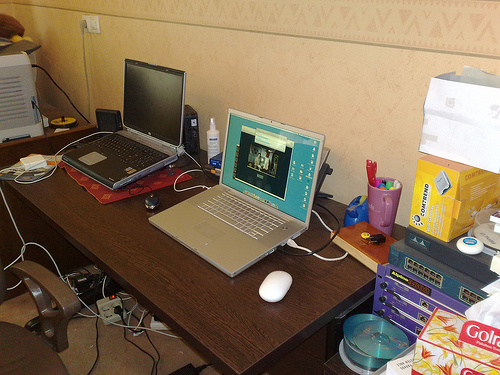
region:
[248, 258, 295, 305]
mouse on the desk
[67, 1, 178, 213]
Black laptop on the desk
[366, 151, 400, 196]
markers in the cup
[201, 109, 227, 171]
bottle on the desk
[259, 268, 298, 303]
The white mouse on the table.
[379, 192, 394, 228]
The handle of the purple cup.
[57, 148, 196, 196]
The red mat under the laptop.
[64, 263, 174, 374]
The wires under the table.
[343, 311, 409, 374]
The stack of CDs on the side table.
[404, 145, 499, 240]
The yellow box on the right.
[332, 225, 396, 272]
The book in front of the purple cup.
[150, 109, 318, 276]
The laptop on the right.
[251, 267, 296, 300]
white mouse on the desk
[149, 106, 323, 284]
open silver laptop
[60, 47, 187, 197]
open black and silver laptop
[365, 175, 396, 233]
purple cup on the table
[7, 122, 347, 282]
cords on the desk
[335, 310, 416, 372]
spindle of blue cds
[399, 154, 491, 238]
yellow cardboard box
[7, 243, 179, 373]
cords on the floor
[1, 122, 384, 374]
brown wooden desk the laptops are on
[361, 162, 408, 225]
coffee mug with pens inside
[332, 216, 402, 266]
book on the desk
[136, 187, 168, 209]
Blue mouse on the desk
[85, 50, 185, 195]
silver and black laptop on the desk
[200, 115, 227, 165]
white bottle on the desk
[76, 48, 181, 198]
computer system on the desk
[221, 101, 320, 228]
power on the laptop screen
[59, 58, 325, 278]
Laptops sitting on a table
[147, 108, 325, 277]
Laptop that is turned on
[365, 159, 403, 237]
Scissors and pens in a purple coffee cup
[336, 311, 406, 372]
CDR's sitting to the right of the table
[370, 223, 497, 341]
A pile of unused networking equipment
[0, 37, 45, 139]
Gray and white printer sitting next to the laptops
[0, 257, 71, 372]
Brown office chair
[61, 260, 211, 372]
Tangle of cords under the table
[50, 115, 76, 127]
Stack of CD's sitting behind the printer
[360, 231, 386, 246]
Single black binder clip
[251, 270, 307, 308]
white cordless mouse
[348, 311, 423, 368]
circular blue cd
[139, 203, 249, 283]
silver color on lap top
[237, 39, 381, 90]
brown paint on wall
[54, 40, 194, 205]
black and silver lap top on table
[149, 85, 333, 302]
silver lap top on table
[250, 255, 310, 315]
white mouse on table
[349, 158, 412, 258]
pink cup on table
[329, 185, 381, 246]
blue tape holder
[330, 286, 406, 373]
stack of cd's on table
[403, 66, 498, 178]
white box on boxes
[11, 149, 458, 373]
dark wood table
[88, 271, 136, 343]
white plugs on floor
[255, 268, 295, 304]
little mouse white on table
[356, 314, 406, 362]
compact disc green and grey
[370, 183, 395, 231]
pink cup with handle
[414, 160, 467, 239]
small yellow cardboard box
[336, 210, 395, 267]
orange old book on the table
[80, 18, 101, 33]
Electric wall jack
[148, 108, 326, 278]
silver Apple laptop computer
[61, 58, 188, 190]
gray and black laptop computer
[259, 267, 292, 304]
cordless white mouse on the desk top